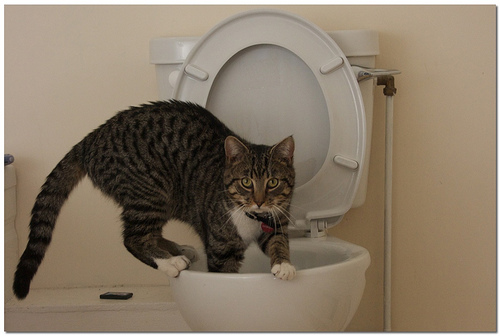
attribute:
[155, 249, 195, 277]
paw — back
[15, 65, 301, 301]
cat — grey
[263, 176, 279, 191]
eye — green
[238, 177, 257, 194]
eye — green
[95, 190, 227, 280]
legs — back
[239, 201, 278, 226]
collar — black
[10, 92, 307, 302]
cat — silver, black, brown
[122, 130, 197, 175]
stripes — black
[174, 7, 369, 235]
toilet seat — up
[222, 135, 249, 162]
ear — pointing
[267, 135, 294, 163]
ear — pointing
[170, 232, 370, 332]
toilet bowl — white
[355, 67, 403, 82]
handle — silver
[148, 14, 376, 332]
toilet — white, ceramic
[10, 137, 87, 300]
tail — long